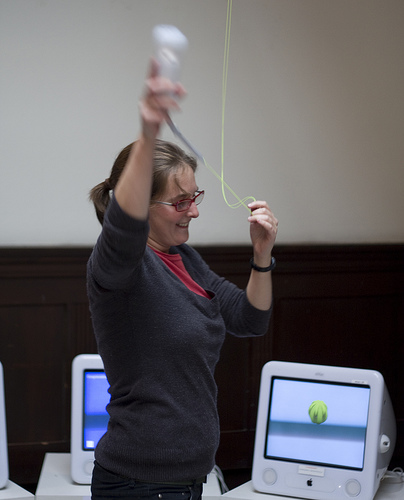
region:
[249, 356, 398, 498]
An Apple computer on the desk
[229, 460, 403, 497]
A desk below the computer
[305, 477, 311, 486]
An Apple logo on the computer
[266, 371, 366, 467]
A monitor on the computer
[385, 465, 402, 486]
Wires next to the computer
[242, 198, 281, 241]
The left hand of the woman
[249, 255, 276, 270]
A watch on her left hand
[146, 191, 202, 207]
The woman is wearing glasses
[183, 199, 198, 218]
The nose of the woman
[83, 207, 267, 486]
The woman is wearing a black shirt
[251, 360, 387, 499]
a primitive CRT monitor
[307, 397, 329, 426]
image of a blue and yellow ball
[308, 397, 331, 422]
image of a yellow and blue ball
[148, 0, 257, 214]
an IV bag with the tubing going too high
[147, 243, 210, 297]
red shirt under a darker sweater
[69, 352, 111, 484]
a partially hidden CRT monitor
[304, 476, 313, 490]
an old logo of Apple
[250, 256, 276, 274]
watch on a woman's wrist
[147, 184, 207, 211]
glasses being worn by a woman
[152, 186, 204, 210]
glasses on a woman's face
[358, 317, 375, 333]
part of a wall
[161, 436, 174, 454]
part of a sweater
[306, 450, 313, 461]
part of a screen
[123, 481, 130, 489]
part of a jeans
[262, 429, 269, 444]
edge of a screen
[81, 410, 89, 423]
part of a screen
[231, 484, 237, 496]
part of a table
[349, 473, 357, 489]
part of a button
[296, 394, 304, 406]
edge of a screen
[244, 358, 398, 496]
White apple computer monitor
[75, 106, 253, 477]
Lady wearing a gray shirt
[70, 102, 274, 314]
Woman smiling and showing teeth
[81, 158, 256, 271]
Woman wearing red glasses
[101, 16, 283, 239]
Woman waving remote control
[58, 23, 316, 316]
Woman holding green string in hand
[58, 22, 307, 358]
Woman wearing low ponytail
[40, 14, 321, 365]
Woman wearing watch on left arm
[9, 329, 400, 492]
Two computer on desks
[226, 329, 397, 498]
Computer monitor turned on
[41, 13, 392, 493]
a woman playing wii in an office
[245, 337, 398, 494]
wii tv screen on a table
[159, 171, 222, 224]
glasses on woman face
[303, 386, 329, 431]
watermelon on a tv screen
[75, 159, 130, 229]
pony tail on the back of a womans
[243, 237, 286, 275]
black watch on womans wrist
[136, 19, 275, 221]
wii remote in a womans left hand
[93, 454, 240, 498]
top of jeans on a woman